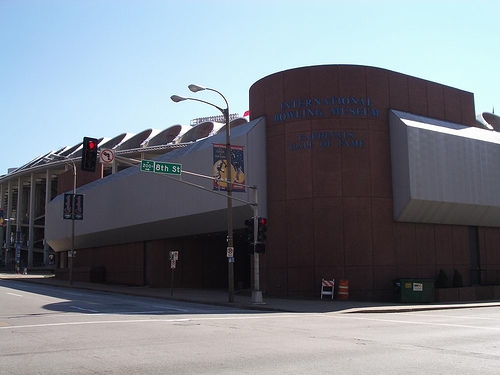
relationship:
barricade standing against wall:
[311, 272, 357, 304] [280, 247, 450, 344]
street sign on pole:
[96, 146, 116, 167] [243, 205, 273, 308]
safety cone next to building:
[331, 273, 353, 305] [34, 61, 499, 299]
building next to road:
[199, 75, 439, 293] [6, 300, 483, 373]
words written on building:
[278, 94, 375, 113] [1, 61, 498, 313]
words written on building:
[326, 104, 382, 118] [1, 61, 498, 313]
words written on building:
[271, 105, 323, 120] [1, 61, 498, 313]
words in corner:
[278, 94, 375, 113] [247, 63, 390, 301]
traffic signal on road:
[242, 211, 264, 309] [0, 280, 499, 374]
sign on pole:
[193, 138, 251, 191] [163, 71, 259, 311]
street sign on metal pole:
[140, 155, 185, 178] [109, 145, 251, 209]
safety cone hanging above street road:
[334, 275, 351, 300] [0, 280, 499, 374]